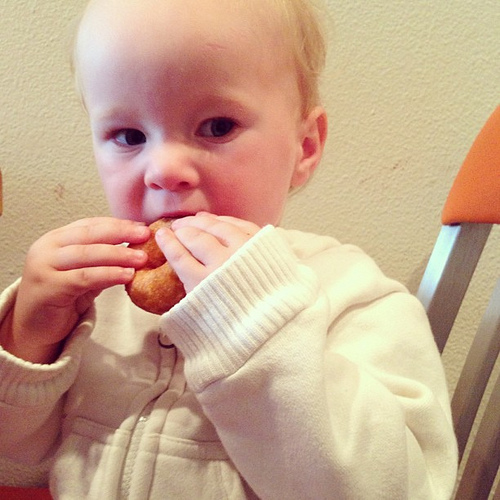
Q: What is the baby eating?
A: A donut.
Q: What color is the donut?
A: Brown.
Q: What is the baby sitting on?
A: A chair.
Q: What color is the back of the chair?
A: Orange.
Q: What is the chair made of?
A: Metal.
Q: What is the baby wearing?
A: A sweater.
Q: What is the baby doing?
A: Eating.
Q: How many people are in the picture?
A: 1.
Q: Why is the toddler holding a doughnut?
A: To eat.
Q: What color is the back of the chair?
A: Orange.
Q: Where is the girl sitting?
A: In a chair.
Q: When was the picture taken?
A: While the toddler was eating a doughnut.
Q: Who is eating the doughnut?
A: A toddler.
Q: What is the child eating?
A: Doughnut.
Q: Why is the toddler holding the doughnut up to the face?
A: To eat the doughnut.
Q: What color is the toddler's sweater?
A: White.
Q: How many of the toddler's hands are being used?
A: 2.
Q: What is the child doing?
A: Eating.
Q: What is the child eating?
A: A donut.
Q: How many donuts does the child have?
A: 1.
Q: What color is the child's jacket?
A: White.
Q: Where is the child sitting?
A: In a chair.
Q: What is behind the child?
A: A wall.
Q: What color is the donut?
A: Brown.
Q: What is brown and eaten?
A: Croissant.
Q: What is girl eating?
A: Brown croissant.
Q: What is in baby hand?
A: Brown croissant to be eaten.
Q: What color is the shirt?
A: White.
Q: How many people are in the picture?
A: One.